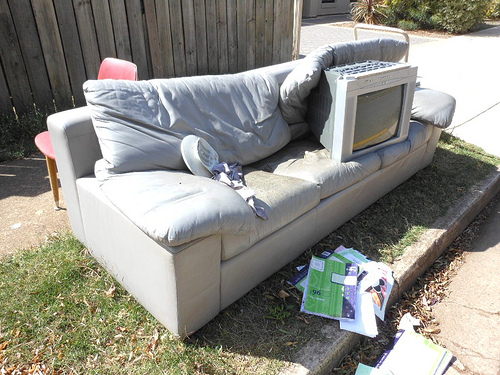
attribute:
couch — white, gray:
[46, 57, 455, 342]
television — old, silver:
[305, 59, 420, 164]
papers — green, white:
[290, 245, 394, 340]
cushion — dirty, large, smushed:
[100, 170, 255, 246]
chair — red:
[35, 57, 138, 208]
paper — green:
[300, 253, 358, 322]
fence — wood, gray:
[0, 0, 294, 126]